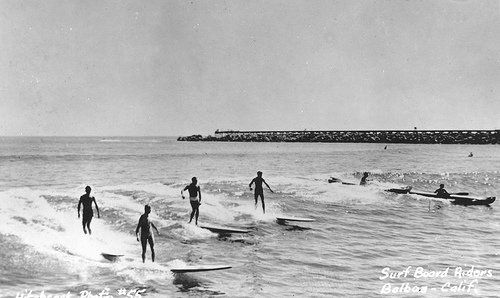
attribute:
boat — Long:
[340, 175, 497, 202]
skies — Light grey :
[81, 20, 396, 94]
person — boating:
[354, 170, 373, 191]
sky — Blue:
[2, 2, 498, 119]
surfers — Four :
[78, 172, 273, 262]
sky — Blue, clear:
[2, 1, 498, 136]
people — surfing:
[60, 163, 293, 273]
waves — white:
[5, 168, 311, 294]